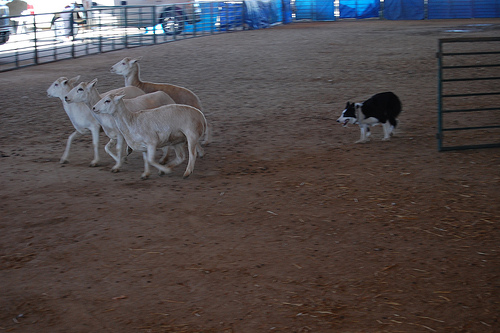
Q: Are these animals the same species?
A: No, there are both sheep and dogs.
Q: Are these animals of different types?
A: Yes, they are sheep and dogs.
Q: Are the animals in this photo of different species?
A: Yes, they are sheep and dogs.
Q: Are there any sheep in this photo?
A: Yes, there is a sheep.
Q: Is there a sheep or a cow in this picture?
A: Yes, there is a sheep.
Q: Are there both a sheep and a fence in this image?
A: Yes, there are both a sheep and a fence.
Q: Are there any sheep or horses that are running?
A: Yes, the sheep is running.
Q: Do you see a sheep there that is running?
A: Yes, there is a sheep that is running.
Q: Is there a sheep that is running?
A: Yes, there is a sheep that is running.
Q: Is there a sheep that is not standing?
A: Yes, there is a sheep that is running.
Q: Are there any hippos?
A: No, there are no hippos.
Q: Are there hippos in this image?
A: No, there are no hippos.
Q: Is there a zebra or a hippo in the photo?
A: No, there are no hippos or zebras.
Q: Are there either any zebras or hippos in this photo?
A: No, there are no hippos or zebras.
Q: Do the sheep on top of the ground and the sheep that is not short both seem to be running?
A: Yes, both the sheep and the sheep are running.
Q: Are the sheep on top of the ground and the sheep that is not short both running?
A: Yes, both the sheep and the sheep are running.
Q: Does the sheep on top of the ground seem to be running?
A: Yes, the sheep is running.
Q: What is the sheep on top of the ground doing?
A: The sheep is running.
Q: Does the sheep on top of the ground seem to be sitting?
A: No, the sheep is running.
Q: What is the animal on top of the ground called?
A: The animal is a sheep.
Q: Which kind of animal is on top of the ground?
A: The animal is a sheep.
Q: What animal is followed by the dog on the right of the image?
A: The sheep is followed by the dog.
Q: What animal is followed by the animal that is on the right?
A: The sheep is followed by the dog.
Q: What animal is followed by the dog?
A: The sheep is followed by the dog.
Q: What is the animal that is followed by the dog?
A: The animal is a sheep.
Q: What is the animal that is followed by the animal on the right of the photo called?
A: The animal is a sheep.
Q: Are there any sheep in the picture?
A: Yes, there is a sheep.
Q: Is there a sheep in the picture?
A: Yes, there is a sheep.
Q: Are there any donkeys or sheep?
A: Yes, there is a sheep.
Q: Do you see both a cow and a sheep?
A: No, there is a sheep but no cows.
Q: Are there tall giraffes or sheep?
A: Yes, there is a tall sheep.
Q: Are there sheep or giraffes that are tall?
A: Yes, the sheep is tall.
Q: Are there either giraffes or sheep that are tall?
A: Yes, the sheep is tall.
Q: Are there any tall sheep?
A: Yes, there is a tall sheep.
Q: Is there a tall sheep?
A: Yes, there is a tall sheep.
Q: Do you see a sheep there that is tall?
A: Yes, there is a sheep that is tall.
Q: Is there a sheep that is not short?
A: Yes, there is a tall sheep.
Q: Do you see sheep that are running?
A: Yes, there is a sheep that is running.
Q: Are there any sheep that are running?
A: Yes, there is a sheep that is running.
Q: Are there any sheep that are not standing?
A: Yes, there is a sheep that is running.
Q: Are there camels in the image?
A: No, there are no camels.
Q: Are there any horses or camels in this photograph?
A: No, there are no camels or horses.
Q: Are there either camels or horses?
A: No, there are no camels or horses.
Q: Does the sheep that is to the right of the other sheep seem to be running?
A: Yes, the sheep is running.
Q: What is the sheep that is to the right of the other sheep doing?
A: The sheep is running.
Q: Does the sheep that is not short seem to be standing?
A: No, the sheep is running.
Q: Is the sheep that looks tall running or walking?
A: The sheep is running.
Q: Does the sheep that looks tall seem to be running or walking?
A: The sheep is running.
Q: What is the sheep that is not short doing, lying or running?
A: The sheep is running.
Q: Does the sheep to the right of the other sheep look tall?
A: Yes, the sheep is tall.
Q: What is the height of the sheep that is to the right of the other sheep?
A: The sheep is tall.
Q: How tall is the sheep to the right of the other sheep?
A: The sheep is tall.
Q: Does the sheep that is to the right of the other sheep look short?
A: No, the sheep is tall.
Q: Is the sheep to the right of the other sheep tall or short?
A: The sheep is tall.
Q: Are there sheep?
A: Yes, there is a sheep.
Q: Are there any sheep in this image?
A: Yes, there is a sheep.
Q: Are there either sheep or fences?
A: Yes, there is a sheep.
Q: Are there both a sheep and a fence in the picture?
A: Yes, there are both a sheep and a fence.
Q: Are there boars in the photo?
A: No, there are no boars.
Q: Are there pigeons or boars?
A: No, there are no boars or pigeons.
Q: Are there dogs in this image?
A: Yes, there is a dog.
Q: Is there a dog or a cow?
A: Yes, there is a dog.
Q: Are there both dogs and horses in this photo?
A: No, there is a dog but no horses.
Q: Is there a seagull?
A: No, there are no seagulls.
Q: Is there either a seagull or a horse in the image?
A: No, there are no seagulls or horses.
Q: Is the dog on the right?
A: Yes, the dog is on the right of the image.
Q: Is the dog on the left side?
A: No, the dog is on the right of the image.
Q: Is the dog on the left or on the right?
A: The dog is on the right of the image.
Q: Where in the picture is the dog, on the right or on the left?
A: The dog is on the right of the image.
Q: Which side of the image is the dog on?
A: The dog is on the right of the image.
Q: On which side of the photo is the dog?
A: The dog is on the right of the image.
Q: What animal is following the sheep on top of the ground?
A: The dog is following the sheep.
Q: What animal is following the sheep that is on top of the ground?
A: The animal is a dog.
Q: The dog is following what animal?
A: The dog is following the sheep.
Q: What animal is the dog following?
A: The dog is following the sheep.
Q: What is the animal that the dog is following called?
A: The animal is a sheep.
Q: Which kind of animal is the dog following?
A: The dog is following the sheep.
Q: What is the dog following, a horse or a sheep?
A: The dog is following a sheep.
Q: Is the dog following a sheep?
A: Yes, the dog is following a sheep.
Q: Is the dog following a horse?
A: No, the dog is following a sheep.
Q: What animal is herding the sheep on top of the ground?
A: The dog is herding the sheep.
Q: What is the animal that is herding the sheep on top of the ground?
A: The animal is a dog.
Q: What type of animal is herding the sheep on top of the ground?
A: The animal is a dog.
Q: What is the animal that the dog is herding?
A: The animal is a sheep.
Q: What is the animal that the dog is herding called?
A: The animal is a sheep.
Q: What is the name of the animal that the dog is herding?
A: The animal is a sheep.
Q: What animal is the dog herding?
A: The dog is herding the sheep.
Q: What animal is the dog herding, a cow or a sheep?
A: The dog is herding a sheep.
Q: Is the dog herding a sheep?
A: Yes, the dog is herding a sheep.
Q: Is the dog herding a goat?
A: No, the dog is herding a sheep.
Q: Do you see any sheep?
A: Yes, there is a sheep.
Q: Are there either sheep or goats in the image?
A: Yes, there is a sheep.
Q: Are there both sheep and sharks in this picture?
A: No, there is a sheep but no sharks.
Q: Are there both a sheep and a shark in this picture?
A: No, there is a sheep but no sharks.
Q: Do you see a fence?
A: Yes, there is a fence.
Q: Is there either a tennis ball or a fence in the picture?
A: Yes, there is a fence.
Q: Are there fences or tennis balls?
A: Yes, there is a fence.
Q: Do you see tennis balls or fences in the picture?
A: Yes, there is a fence.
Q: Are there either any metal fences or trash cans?
A: Yes, there is a metal fence.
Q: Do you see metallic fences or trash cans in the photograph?
A: Yes, there is a metal fence.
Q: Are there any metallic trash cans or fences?
A: Yes, there is a metal fence.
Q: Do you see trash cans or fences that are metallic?
A: Yes, the fence is metallic.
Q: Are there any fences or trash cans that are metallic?
A: Yes, the fence is metallic.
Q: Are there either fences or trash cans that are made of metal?
A: Yes, the fence is made of metal.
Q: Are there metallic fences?
A: Yes, there is a metal fence.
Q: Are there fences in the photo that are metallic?
A: Yes, there is a metal fence.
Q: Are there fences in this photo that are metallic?
A: Yes, there is a fence that is metallic.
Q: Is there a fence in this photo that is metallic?
A: Yes, there is a fence that is metallic.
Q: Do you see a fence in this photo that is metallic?
A: Yes, there is a fence that is metallic.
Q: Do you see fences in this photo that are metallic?
A: Yes, there is a fence that is metallic.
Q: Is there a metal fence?
A: Yes, there is a fence that is made of metal.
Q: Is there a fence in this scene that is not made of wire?
A: Yes, there is a fence that is made of metal.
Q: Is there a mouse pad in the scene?
A: No, there are no mouse pads.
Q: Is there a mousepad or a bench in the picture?
A: No, there are no mouse pads or benches.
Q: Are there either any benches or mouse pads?
A: No, there are no mouse pads or benches.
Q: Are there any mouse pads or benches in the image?
A: No, there are no mouse pads or benches.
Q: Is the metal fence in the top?
A: Yes, the fence is in the top of the image.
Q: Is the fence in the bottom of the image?
A: No, the fence is in the top of the image.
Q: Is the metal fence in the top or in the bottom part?
A: The fence is in the top of the image.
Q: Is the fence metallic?
A: Yes, the fence is metallic.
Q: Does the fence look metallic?
A: Yes, the fence is metallic.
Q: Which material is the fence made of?
A: The fence is made of metal.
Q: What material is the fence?
A: The fence is made of metal.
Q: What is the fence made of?
A: The fence is made of metal.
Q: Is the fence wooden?
A: No, the fence is metallic.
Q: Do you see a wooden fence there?
A: No, there is a fence but it is metallic.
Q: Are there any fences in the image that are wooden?
A: No, there is a fence but it is metallic.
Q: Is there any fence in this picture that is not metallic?
A: No, there is a fence but it is metallic.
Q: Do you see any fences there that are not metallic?
A: No, there is a fence but it is metallic.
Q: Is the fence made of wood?
A: No, the fence is made of metal.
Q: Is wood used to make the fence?
A: No, the fence is made of metal.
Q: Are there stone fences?
A: No, there is a fence but it is made of metal.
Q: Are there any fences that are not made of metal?
A: No, there is a fence but it is made of metal.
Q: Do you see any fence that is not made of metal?
A: No, there is a fence but it is made of metal.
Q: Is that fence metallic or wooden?
A: The fence is metallic.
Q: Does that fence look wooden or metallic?
A: The fence is metallic.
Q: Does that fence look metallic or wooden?
A: The fence is metallic.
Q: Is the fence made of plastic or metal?
A: The fence is made of metal.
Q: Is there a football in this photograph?
A: No, there are no footballs.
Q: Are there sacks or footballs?
A: No, there are no footballs or sacks.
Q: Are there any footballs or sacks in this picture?
A: No, there are no footballs or sacks.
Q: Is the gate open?
A: Yes, the gate is open.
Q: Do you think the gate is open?
A: Yes, the gate is open.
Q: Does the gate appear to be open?
A: Yes, the gate is open.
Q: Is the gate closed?
A: No, the gate is open.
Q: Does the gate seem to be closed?
A: No, the gate is open.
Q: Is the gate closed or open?
A: The gate is open.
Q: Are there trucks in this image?
A: Yes, there is a truck.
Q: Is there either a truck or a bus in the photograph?
A: Yes, there is a truck.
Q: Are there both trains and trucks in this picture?
A: No, there is a truck but no trains.